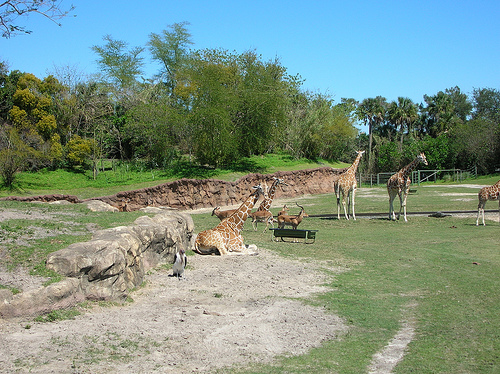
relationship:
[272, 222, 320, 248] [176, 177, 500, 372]
bench on ground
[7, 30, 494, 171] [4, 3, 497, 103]
trees below sky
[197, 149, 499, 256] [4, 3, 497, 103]
giraffes below sky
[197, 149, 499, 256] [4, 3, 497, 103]
giraffes under sky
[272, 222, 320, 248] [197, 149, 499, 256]
bench near giraffes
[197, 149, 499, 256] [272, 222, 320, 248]
giraffes near bench